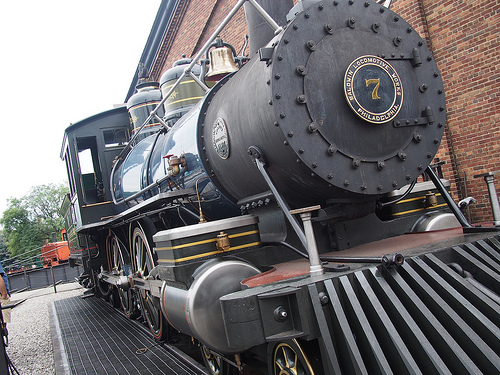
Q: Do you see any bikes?
A: No, there are no bikes.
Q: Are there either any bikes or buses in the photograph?
A: No, there are no bikes or buses.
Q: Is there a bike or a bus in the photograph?
A: No, there are no bikes or buses.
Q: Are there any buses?
A: No, there are no buses.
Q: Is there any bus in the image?
A: No, there are no buses.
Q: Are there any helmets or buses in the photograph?
A: No, there are no buses or helmets.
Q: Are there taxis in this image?
A: No, there are no taxis.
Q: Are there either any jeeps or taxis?
A: No, there are no taxis or jeeps.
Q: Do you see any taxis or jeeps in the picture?
A: No, there are no taxis or jeeps.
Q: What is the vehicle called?
A: The vehicle is a locomotive.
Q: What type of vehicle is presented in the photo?
A: The vehicle is a locomotive.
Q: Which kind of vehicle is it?
A: The vehicle is a locomotive.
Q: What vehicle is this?
A: This is a locomotive.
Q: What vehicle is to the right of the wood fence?
A: The vehicle is a locomotive.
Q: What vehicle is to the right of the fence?
A: The vehicle is a locomotive.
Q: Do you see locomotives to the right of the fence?
A: Yes, there is a locomotive to the right of the fence.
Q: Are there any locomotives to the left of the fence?
A: No, the locomotive is to the right of the fence.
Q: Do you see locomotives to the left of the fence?
A: No, the locomotive is to the right of the fence.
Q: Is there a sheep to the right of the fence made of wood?
A: No, there is a locomotive to the right of the fence.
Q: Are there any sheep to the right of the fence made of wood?
A: No, there is a locomotive to the right of the fence.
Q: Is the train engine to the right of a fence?
A: Yes, the train engine is to the right of a fence.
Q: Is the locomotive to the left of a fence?
A: No, the locomotive is to the right of a fence.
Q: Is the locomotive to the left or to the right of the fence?
A: The locomotive is to the right of the fence.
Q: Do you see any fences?
A: Yes, there is a fence.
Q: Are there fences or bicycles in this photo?
A: Yes, there is a fence.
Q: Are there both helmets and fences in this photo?
A: No, there is a fence but no helmets.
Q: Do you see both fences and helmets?
A: No, there is a fence but no helmets.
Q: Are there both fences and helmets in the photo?
A: No, there is a fence but no helmets.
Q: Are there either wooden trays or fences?
A: Yes, there is a wood fence.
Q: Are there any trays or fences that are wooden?
A: Yes, the fence is wooden.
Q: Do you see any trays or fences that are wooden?
A: Yes, the fence is wooden.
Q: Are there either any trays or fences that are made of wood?
A: Yes, the fence is made of wood.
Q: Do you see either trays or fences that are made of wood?
A: Yes, the fence is made of wood.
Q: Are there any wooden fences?
A: Yes, there is a wood fence.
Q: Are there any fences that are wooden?
A: Yes, there is a fence that is wooden.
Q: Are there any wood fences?
A: Yes, there is a fence that is made of wood.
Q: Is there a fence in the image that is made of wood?
A: Yes, there is a fence that is made of wood.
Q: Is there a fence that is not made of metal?
A: Yes, there is a fence that is made of wood.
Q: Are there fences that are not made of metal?
A: Yes, there is a fence that is made of wood.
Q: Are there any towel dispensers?
A: No, there are no towel dispensers.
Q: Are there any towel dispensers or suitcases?
A: No, there are no towel dispensers or suitcases.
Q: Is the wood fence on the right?
A: No, the fence is on the left of the image.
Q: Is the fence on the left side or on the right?
A: The fence is on the left of the image.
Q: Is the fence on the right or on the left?
A: The fence is on the left of the image.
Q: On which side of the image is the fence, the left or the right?
A: The fence is on the left of the image.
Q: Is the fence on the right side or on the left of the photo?
A: The fence is on the left of the image.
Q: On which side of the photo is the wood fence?
A: The fence is on the left of the image.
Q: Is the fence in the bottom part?
A: Yes, the fence is in the bottom of the image.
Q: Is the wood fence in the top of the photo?
A: No, the fence is in the bottom of the image.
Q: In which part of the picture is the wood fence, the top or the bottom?
A: The fence is in the bottom of the image.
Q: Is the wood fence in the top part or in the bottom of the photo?
A: The fence is in the bottom of the image.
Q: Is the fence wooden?
A: Yes, the fence is wooden.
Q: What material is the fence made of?
A: The fence is made of wood.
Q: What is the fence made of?
A: The fence is made of wood.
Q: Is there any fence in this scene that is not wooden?
A: No, there is a fence but it is wooden.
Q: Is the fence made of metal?
A: No, the fence is made of wood.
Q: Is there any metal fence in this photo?
A: No, there is a fence but it is made of wood.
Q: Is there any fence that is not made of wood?
A: No, there is a fence but it is made of wood.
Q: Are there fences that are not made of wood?
A: No, there is a fence but it is made of wood.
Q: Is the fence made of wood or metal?
A: The fence is made of wood.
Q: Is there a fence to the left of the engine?
A: Yes, there is a fence to the left of the engine.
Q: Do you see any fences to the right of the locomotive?
A: No, the fence is to the left of the locomotive.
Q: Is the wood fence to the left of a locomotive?
A: Yes, the fence is to the left of a locomotive.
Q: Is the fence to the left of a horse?
A: No, the fence is to the left of a locomotive.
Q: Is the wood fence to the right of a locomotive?
A: No, the fence is to the left of a locomotive.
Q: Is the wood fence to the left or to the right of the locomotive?
A: The fence is to the left of the locomotive.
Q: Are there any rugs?
A: No, there are no rugs.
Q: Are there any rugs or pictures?
A: No, there are no rugs or pictures.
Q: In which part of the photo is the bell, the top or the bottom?
A: The bell is in the top of the image.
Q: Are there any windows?
A: Yes, there is a window.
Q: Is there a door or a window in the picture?
A: Yes, there is a window.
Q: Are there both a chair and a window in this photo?
A: No, there is a window but no chairs.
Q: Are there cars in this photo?
A: No, there are no cars.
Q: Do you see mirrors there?
A: No, there are no mirrors.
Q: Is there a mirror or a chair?
A: No, there are no mirrors or chairs.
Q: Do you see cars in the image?
A: No, there are no cars.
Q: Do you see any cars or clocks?
A: No, there are no cars or clocks.